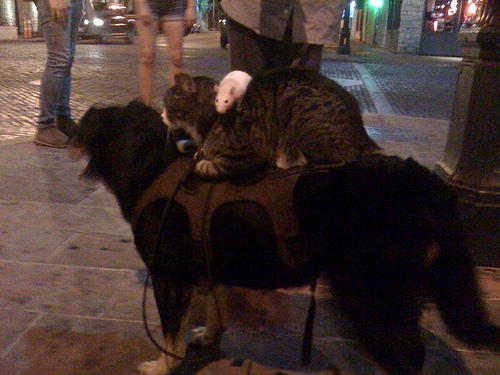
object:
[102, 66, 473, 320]
animals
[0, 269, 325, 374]
sidewalk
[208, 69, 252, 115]
mouse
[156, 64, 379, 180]
cat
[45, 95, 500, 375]
dog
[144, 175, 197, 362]
leash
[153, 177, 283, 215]
halter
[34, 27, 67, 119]
jean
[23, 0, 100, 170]
person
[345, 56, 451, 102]
road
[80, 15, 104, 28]
headlight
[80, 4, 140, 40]
car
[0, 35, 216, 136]
street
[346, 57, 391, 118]
line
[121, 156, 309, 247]
vest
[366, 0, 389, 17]
light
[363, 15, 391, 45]
wall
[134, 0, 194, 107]
woman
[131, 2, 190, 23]
shorts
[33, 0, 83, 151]
man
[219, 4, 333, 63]
person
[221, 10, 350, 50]
trenchcoat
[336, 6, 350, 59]
poles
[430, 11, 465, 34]
window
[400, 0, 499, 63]
store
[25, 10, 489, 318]
picture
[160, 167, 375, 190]
back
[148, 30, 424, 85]
top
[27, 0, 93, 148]
people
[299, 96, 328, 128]
stripes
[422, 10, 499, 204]
lampost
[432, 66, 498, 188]
base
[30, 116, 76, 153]
shoe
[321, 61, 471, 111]
roadway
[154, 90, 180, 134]
face